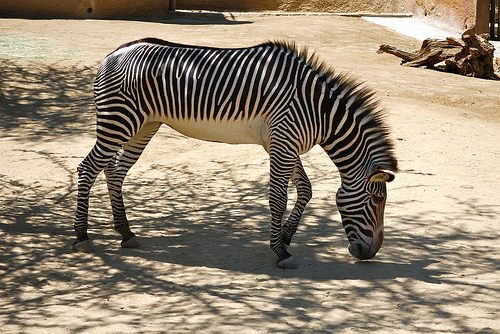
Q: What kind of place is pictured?
A: It is a field.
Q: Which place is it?
A: It is a field.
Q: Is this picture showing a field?
A: Yes, it is showing a field.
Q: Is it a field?
A: Yes, it is a field.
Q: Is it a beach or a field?
A: It is a field.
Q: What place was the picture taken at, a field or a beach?
A: It was taken at a field.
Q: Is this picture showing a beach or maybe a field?
A: It is showing a field.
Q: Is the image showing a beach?
A: No, the picture is showing a field.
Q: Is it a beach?
A: No, it is a field.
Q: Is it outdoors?
A: Yes, it is outdoors.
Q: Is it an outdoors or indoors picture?
A: It is outdoors.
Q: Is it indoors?
A: No, it is outdoors.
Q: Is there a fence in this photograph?
A: No, there are no fences.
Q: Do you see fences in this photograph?
A: No, there are no fences.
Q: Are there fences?
A: No, there are no fences.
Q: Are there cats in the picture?
A: No, there are no cats.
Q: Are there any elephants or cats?
A: No, there are no cats or elephants.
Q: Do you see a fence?
A: No, there are no fences.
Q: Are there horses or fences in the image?
A: No, there are no fences or horses.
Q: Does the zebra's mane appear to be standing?
A: Yes, the mane is standing.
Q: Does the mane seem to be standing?
A: Yes, the mane is standing.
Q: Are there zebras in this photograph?
A: Yes, there is a zebra.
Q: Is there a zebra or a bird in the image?
A: Yes, there is a zebra.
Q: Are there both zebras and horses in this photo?
A: No, there is a zebra but no horses.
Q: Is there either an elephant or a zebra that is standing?
A: Yes, the zebra is standing.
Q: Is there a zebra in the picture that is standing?
A: Yes, there is a zebra that is standing.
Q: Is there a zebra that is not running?
A: Yes, there is a zebra that is standing.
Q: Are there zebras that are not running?
A: Yes, there is a zebra that is standing.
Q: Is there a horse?
A: No, there are no horses.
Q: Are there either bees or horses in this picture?
A: No, there are no horses or bees.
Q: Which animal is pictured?
A: The animal is a zebra.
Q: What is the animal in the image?
A: The animal is a zebra.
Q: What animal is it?
A: The animal is a zebra.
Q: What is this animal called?
A: This is a zebra.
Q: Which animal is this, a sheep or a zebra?
A: This is a zebra.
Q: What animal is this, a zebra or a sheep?
A: This is a zebra.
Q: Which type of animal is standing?
A: The animal is a zebra.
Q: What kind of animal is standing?
A: The animal is a zebra.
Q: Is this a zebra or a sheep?
A: This is a zebra.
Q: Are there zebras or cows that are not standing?
A: No, there is a zebra but it is standing.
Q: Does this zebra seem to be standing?
A: Yes, the zebra is standing.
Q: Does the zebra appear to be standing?
A: Yes, the zebra is standing.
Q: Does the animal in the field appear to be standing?
A: Yes, the zebra is standing.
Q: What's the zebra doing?
A: The zebra is standing.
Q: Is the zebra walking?
A: No, the zebra is standing.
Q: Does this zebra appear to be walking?
A: No, the zebra is standing.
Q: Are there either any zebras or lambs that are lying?
A: No, there is a zebra but it is standing.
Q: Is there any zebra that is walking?
A: No, there is a zebra but it is standing.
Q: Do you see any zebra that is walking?
A: No, there is a zebra but it is standing.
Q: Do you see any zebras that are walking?
A: No, there is a zebra but it is standing.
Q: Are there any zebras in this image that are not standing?
A: No, there is a zebra but it is standing.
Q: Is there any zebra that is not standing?
A: No, there is a zebra but it is standing.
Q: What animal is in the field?
A: The animal is a zebra.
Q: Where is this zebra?
A: The zebra is in the field.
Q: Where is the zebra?
A: The zebra is in the field.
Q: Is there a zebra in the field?
A: Yes, there is a zebra in the field.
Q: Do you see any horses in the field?
A: No, there is a zebra in the field.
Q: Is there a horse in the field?
A: No, there is a zebra in the field.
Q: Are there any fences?
A: No, there are no fences.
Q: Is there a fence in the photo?
A: No, there are no fences.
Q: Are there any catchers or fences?
A: No, there are no fences or catchers.